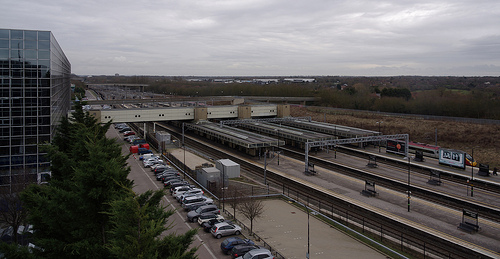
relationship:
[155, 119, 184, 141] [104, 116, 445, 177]
entrance to station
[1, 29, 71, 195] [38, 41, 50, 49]
building with window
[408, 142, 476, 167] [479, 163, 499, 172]
train on track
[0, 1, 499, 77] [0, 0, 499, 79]
sky with clouds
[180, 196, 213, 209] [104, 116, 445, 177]
car at station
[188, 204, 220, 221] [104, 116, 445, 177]
car at station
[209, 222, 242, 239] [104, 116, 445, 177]
car at station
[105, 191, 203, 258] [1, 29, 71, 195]
tree next to building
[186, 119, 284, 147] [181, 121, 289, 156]
awning covering platform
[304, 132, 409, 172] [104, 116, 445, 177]
structure outside station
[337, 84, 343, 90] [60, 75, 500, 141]
tree in distance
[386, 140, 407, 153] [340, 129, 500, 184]
sign on platform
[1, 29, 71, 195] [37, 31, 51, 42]
building with window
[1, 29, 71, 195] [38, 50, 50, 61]
building with window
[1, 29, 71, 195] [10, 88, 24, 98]
building with window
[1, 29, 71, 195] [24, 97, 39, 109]
building with window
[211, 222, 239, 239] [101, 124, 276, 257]
car parked in lot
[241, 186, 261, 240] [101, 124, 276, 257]
tree in lot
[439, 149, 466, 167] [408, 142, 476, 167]
sign next to train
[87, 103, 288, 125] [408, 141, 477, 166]
bridge connecting train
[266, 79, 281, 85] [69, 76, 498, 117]
building in background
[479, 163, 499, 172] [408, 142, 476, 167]
track for train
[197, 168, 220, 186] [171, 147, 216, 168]
box for building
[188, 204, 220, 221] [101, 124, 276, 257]
car in area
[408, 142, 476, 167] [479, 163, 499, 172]
train moving on track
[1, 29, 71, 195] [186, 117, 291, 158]
building across from terminal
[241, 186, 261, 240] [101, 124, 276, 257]
tree next to area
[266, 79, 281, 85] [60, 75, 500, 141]
building in distance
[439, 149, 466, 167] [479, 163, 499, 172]
sign on side of track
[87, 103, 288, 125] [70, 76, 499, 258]
building above ground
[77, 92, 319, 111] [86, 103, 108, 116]
overpass above road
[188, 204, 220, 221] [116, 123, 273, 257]
car parked in row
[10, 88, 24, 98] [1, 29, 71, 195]
window on building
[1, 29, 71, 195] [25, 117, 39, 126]
building made of glass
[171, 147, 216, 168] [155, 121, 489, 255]
building by track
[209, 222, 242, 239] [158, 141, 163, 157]
car parked by gate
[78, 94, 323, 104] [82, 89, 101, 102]
overpass above freeway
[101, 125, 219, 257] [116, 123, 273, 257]
street for cars